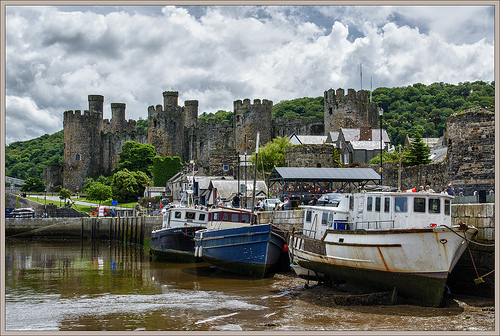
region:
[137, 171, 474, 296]
four boats at dock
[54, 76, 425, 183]
towers of a castle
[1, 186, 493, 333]
boats in murky water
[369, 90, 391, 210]
a street light by the water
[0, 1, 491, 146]
a sky filled with clouds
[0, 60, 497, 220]
a hillside covered with trees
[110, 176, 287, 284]
two blue boats together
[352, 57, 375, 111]
two towers atop a hill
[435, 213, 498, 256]
a rope tying up the boat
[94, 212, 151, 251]
wooden posts used as shock absorbers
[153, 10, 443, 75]
Stormy sky overhead scene.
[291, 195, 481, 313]
Boat run aground today.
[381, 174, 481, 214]
Bridge onlookers look harbor.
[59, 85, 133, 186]
Ancient castle turrets rustic.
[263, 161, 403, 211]
Tourists use available Bandstand.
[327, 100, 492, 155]
Colorful streamers strung town.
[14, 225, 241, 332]
Murky harbor water dingy.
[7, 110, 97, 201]
Background foliage abundant.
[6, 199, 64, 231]
Vehicle barely seen roadway.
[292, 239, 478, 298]
Rust covered boat bottom.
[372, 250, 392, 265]
brown rust on white boat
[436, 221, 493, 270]
long thick black cord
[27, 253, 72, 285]
reflection into brown water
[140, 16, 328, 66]
large fluffy white clouds in the sky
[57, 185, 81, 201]
small green tree on shore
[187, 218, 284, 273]
blue boat in brown water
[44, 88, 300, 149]
old castles in the background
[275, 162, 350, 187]
blue roof on brown stone building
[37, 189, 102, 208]
long paved gray road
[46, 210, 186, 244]
gray bridge over water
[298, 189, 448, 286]
a grounded white boat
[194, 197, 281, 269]
a grounded blue boat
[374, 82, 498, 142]
a group of green trees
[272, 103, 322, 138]
another green tree clump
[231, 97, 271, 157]
a stone castle turret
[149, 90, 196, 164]
a group of castle turrets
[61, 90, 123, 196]
another group of turrets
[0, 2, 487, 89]
a bunch of white clouds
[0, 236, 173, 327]
a shallow pond of water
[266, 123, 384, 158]
a small group of buildings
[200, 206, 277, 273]
a blue boat sitting in the water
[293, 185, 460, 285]
a white boat sitting in the water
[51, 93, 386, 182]
the castle sitting by the side of a hill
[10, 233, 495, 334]
the dirty water of a river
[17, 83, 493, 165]
the plants and trees of a hill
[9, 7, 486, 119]
a cloudy sky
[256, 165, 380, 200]
a gazebo with flags on it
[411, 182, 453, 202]
people standing around looking at the boats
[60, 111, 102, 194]
a castle tower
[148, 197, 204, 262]
a black and white boat